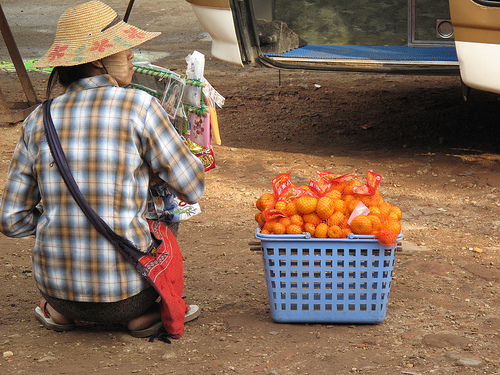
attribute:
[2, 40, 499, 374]
ground — brown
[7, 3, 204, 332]
woman — sitting, selling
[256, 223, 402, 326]
basket — blue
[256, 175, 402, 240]
oranges — orange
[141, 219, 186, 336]
bag — red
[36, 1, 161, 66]
hat — straw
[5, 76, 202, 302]
shirt — plaid